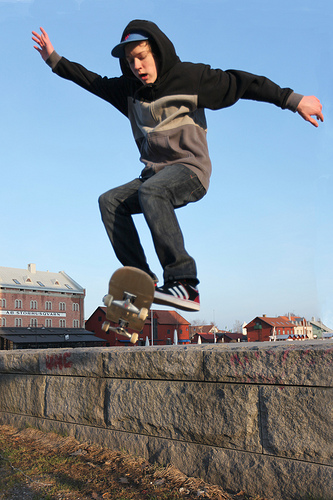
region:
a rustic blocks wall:
[13, 351, 331, 480]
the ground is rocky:
[18, 441, 136, 491]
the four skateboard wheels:
[102, 294, 147, 343]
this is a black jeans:
[101, 167, 206, 283]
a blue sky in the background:
[179, 4, 318, 38]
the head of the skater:
[119, 30, 167, 85]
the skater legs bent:
[97, 168, 203, 280]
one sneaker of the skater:
[151, 279, 202, 309]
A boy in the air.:
[30, 18, 323, 312]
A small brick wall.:
[1, 339, 331, 499]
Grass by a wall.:
[0, 423, 266, 499]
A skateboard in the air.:
[99, 265, 155, 345]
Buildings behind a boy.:
[1, 262, 332, 350]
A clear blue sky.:
[0, 1, 332, 334]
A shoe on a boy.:
[154, 278, 201, 312]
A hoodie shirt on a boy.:
[44, 18, 303, 193]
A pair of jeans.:
[97, 162, 206, 286]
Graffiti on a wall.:
[42, 352, 72, 371]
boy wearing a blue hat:
[104, 24, 160, 66]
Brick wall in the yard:
[10, 336, 329, 482]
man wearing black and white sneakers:
[153, 280, 195, 308]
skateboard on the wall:
[94, 266, 162, 346]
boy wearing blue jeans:
[102, 160, 201, 275]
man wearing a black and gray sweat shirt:
[22, 34, 306, 172]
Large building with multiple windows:
[7, 260, 85, 323]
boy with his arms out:
[24, 24, 324, 135]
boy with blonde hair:
[131, 34, 156, 57]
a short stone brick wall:
[0, 343, 332, 496]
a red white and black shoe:
[150, 281, 201, 311]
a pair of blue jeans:
[98, 165, 205, 284]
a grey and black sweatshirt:
[45, 16, 306, 187]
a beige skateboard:
[101, 266, 156, 342]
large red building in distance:
[244, 315, 293, 343]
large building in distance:
[1, 261, 87, 329]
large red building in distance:
[86, 304, 189, 344]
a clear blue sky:
[1, 0, 331, 333]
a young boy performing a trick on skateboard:
[30, 18, 326, 341]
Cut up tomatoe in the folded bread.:
[36, 399, 91, 444]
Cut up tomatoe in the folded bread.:
[215, 310, 319, 338]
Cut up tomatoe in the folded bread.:
[154, 141, 169, 148]